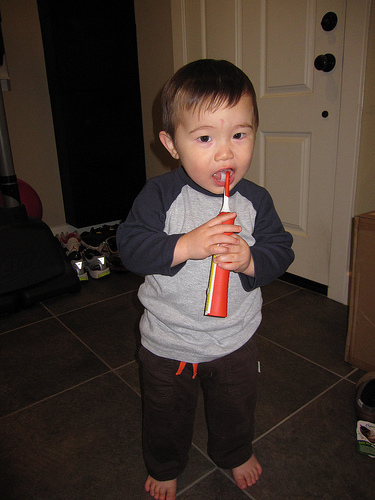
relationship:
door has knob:
[172, 0, 356, 303] [316, 51, 332, 72]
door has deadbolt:
[172, 0, 356, 303] [320, 8, 338, 33]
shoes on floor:
[55, 222, 120, 283] [0, 280, 374, 500]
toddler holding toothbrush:
[117, 61, 297, 497] [205, 170, 237, 321]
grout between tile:
[253, 377, 348, 453] [116, 322, 341, 472]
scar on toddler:
[219, 121, 227, 133] [117, 61, 297, 497]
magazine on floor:
[355, 421, 373, 461] [0, 280, 374, 500]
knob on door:
[316, 51, 332, 72] [172, 0, 356, 303]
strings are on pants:
[175, 362, 202, 379] [140, 338, 258, 480]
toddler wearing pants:
[117, 61, 297, 497] [140, 338, 258, 480]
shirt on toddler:
[116, 173, 294, 366] [117, 61, 297, 497]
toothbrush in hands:
[205, 170, 237, 321] [192, 212, 254, 275]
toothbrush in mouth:
[205, 170, 237, 321] [212, 167, 241, 188]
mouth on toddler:
[212, 167, 241, 188] [117, 61, 297, 497]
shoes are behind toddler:
[55, 222, 120, 283] [117, 61, 297, 497]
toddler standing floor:
[117, 61, 297, 497] [0, 280, 374, 500]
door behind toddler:
[172, 0, 356, 303] [117, 61, 297, 497]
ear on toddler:
[158, 130, 179, 162] [117, 61, 297, 497]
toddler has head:
[117, 61, 297, 497] [162, 58, 260, 195]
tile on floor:
[116, 322, 341, 472] [0, 280, 374, 500]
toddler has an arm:
[117, 61, 297, 497] [253, 192, 295, 290]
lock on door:
[320, 8, 338, 33] [172, 0, 356, 303]